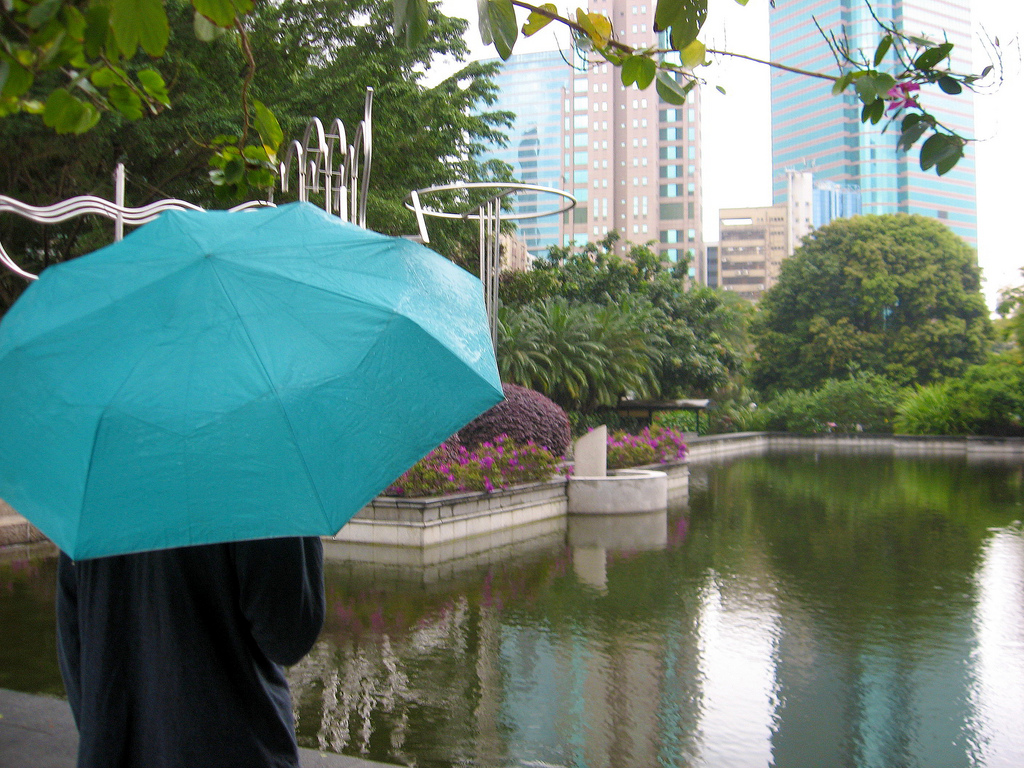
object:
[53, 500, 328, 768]
people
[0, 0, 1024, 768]
outdoors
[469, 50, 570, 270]
building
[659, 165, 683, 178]
window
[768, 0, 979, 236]
building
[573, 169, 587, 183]
window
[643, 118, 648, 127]
window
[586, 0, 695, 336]
building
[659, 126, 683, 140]
window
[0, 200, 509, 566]
umbrella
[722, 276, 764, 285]
windows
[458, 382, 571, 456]
flowers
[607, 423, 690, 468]
flowers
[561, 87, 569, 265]
building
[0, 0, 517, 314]
tree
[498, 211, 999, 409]
bush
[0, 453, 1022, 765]
water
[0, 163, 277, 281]
sculpture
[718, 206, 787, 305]
building